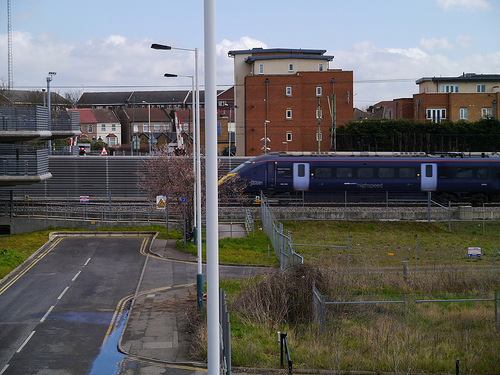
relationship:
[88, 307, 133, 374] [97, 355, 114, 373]
puddle of water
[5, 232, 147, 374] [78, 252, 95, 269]
pavement has stripes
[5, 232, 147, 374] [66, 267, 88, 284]
pavement has stripes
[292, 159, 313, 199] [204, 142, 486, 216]
door of train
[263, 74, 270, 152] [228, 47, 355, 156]
pole on building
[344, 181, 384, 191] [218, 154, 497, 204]
writing on side of train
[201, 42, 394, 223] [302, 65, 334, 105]
building with window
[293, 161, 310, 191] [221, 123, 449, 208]
door on train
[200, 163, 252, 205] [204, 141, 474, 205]
nose of train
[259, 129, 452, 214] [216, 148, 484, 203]
windows on train